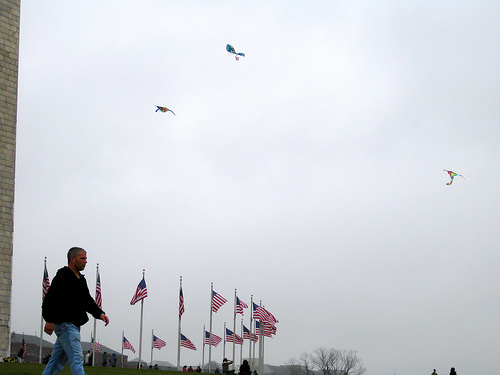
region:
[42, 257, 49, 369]
american flag on a pole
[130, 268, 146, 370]
american flag on a pole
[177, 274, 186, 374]
american flag on a pole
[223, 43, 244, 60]
a kite in the air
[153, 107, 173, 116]
a kite in the air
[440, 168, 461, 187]
a kite in the air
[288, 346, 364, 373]
top of a leafless tree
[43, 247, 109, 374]
a man is walking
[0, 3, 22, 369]
edge of a brick building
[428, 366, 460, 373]
people are standing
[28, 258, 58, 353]
American flag around Washington Monument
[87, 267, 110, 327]
American flag around Washington Monument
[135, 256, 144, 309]
American flag around Washington Monument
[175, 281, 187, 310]
American flag around Washington Monument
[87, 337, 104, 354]
American flag around Washington Monument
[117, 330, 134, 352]
American flag around Washington Monument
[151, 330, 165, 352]
American flag around Washington Monument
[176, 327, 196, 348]
American flag around Washington Monument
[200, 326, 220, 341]
American flag around Washington Monument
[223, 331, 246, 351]
American flag around Washington Monument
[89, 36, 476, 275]
the sky is overcast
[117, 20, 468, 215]
kites are flying in the sky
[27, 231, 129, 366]
the man is walking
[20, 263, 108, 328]
the shirt is black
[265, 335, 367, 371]
the trees are bare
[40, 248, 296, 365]
many flags are flying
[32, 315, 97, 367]
the jeans are blue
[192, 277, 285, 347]
the flags are blowing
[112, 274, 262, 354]
the flags are in motion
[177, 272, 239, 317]
the flag is red, white, and blue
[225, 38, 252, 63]
a colorful kite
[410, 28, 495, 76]
part of a blue sky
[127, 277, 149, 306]
a red, white and blue flag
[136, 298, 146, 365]
a long gray pole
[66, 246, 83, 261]
a man's short cut gray hair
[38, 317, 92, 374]
a man's blue jean pants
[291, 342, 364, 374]
part of a tree with no leaves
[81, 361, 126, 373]
a portion of green grass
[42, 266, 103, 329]
a man's black jacket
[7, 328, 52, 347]
the roof of a building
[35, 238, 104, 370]
A man walking on grass.,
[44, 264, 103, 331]
A black jacket on a man.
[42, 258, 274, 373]
A row of American Flags.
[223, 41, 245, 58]
A blue kite in the sky.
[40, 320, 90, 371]
Blue denim jeans on a man.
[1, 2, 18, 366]
A tan brick building.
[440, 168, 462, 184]
A rainbow kite in the sky.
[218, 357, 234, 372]
A person with hand on face.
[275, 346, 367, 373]
A tree with no leaves.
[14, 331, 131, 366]
A building in background.